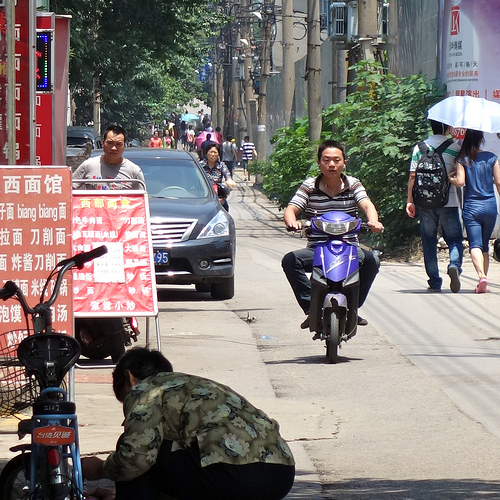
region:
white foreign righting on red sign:
[43, 173, 65, 193]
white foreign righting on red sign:
[23, 174, 42, 196]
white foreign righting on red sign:
[3, 175, 23, 195]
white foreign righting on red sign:
[55, 198, 66, 218]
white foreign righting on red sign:
[5, 201, 15, 217]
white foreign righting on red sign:
[7, 252, 20, 268]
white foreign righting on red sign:
[20, 250, 32, 266]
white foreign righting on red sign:
[88, 300, 99, 310]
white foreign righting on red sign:
[100, 296, 115, 311]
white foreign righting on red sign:
[125, 300, 139, 312]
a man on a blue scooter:
[288, 158, 383, 342]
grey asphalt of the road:
[328, 370, 487, 470]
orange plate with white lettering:
[26, 417, 76, 447]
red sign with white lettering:
[0, 176, 72, 314]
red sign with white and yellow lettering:
[77, 186, 151, 308]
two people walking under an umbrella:
[413, 89, 499, 266]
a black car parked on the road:
[132, 150, 244, 294]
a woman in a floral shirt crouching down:
[85, 366, 306, 488]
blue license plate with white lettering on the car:
[149, 248, 174, 270]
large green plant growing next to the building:
[286, 88, 428, 245]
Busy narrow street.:
[183, 107, 318, 497]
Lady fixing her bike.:
[85, 325, 295, 490]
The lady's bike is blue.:
[7, 245, 92, 496]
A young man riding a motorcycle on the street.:
[280, 140, 385, 351]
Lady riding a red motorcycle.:
[197, 140, 228, 210]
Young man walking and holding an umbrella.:
[405, 95, 465, 290]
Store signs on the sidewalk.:
[0, 160, 160, 361]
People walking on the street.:
[150, 110, 255, 151]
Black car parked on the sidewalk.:
[62, 145, 232, 295]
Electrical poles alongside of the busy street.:
[205, 2, 408, 203]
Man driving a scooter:
[275, 138, 387, 358]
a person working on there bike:
[6, 242, 308, 496]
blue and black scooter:
[302, 206, 367, 353]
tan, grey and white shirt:
[100, 368, 301, 478]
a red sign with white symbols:
[2, 160, 75, 378]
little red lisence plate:
[32, 423, 77, 448]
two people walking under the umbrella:
[402, 91, 494, 318]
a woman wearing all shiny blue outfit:
[454, 130, 497, 258]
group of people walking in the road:
[140, 108, 252, 178]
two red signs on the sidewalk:
[2, 149, 172, 385]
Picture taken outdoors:
[10, 116, 497, 453]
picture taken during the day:
[26, 138, 476, 486]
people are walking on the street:
[404, 127, 496, 299]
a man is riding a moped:
[292, 133, 388, 370]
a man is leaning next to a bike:
[27, 325, 272, 488]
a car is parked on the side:
[144, 146, 243, 298]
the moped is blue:
[317, 216, 369, 277]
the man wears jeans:
[426, 211, 457, 259]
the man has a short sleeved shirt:
[287, 166, 403, 208]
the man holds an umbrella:
[424, 108, 488, 128]